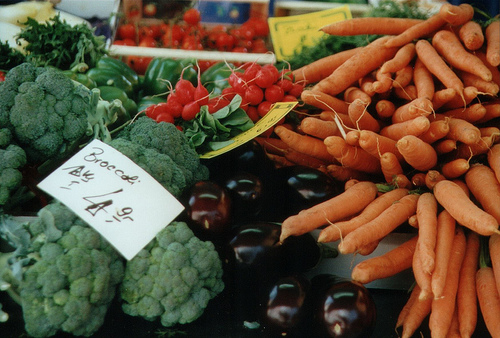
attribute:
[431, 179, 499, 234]
carrot — white, yellow, bunch, orange, raw, fresh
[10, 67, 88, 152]
broccoli — big, green, fresh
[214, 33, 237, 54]
pepper — green, fresh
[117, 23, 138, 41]
strawberry — fresh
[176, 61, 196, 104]
radish — red, leafy, fresh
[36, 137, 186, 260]
paper — price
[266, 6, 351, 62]
sign — yellow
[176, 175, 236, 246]
eggplant — purple